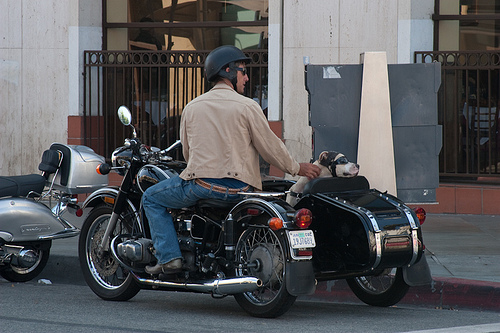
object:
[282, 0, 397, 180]
wall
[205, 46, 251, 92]
helmet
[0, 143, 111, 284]
motorcycle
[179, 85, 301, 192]
jacket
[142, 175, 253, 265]
trouser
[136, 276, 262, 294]
pipe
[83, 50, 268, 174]
gate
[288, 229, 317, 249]
plate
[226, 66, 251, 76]
pair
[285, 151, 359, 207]
dog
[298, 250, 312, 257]
light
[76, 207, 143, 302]
tire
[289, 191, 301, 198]
strap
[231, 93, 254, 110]
shoulder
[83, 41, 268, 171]
railing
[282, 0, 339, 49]
stone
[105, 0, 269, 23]
window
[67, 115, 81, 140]
stripe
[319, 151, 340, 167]
straps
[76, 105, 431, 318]
car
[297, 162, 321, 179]
hand